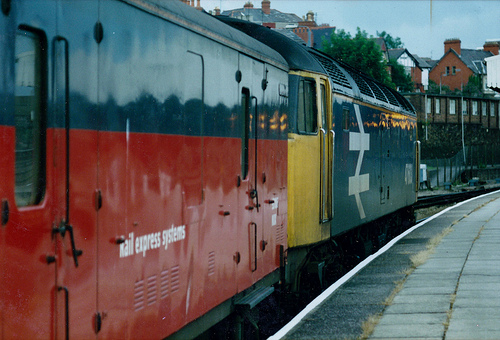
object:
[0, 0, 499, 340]
station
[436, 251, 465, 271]
ground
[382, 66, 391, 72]
teddy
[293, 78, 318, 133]
window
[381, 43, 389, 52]
bear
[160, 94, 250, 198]
wrong picture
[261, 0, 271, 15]
chimney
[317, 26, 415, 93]
green trees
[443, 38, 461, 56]
chimney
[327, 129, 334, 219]
rail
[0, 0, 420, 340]
carrier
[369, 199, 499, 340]
pavement blocks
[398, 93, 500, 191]
fence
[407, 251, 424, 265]
dead grass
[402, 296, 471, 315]
paving stones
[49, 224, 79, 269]
hand rail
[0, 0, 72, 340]
access door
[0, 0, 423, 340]
side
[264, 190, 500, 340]
path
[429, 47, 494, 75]
house roof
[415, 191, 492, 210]
track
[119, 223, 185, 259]
logo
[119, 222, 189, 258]
white words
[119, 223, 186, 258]
name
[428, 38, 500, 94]
building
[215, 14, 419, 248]
car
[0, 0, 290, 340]
car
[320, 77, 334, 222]
door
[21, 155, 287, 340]
reflection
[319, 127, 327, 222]
handle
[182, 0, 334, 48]
buildings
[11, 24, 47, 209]
window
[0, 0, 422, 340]
locomotive